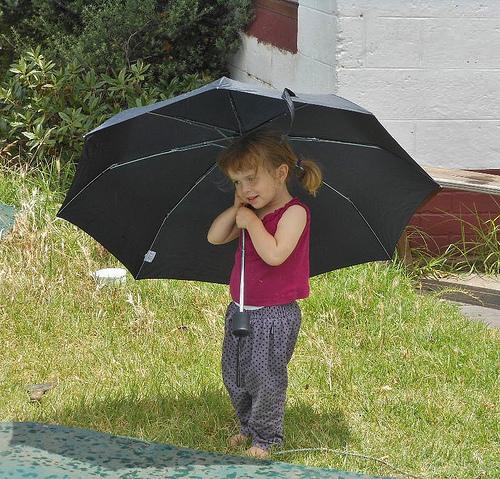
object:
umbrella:
[54, 75, 442, 337]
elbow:
[263, 241, 288, 267]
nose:
[238, 180, 249, 197]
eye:
[245, 175, 257, 182]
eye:
[232, 178, 240, 186]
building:
[225, 1, 499, 310]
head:
[226, 126, 291, 212]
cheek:
[249, 172, 275, 200]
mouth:
[243, 193, 260, 205]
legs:
[242, 319, 306, 458]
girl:
[207, 125, 326, 463]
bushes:
[0, 0, 257, 182]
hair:
[215, 125, 319, 193]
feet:
[239, 443, 271, 462]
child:
[207, 129, 324, 464]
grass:
[0, 158, 499, 478]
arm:
[245, 205, 308, 266]